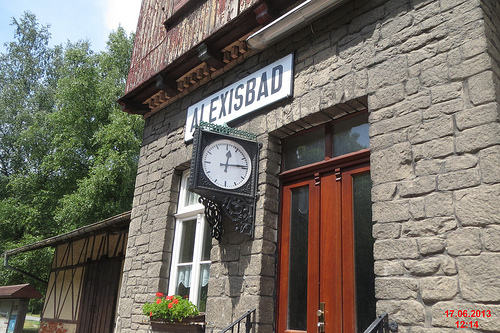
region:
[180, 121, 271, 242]
a metal and white clock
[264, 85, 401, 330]
a red wooden and glass door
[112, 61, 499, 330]
a grey stone building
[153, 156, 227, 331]
window in a stone building with white trim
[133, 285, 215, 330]
box planter with red and green flowers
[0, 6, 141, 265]
leafy green tree tops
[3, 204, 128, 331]
a wooden and tan building with a brown wooden door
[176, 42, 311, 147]
a white sign with black writing saying "ALEXISBAD"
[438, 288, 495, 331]
time stamp with red number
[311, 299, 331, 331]
a brass metal door knob and lock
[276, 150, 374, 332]
A brown front door with two long windows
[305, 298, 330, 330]
Silver lock and handle on the door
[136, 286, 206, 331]
A flower box filled with green leaves and red flowers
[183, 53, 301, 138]
A white sign with black letters that read ALEXISBAD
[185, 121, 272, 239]
An ornate clock on the stone wall front of the building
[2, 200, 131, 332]
A smaller building on the left side of the stone building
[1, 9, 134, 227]
Tall green trees in the background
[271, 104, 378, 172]
Two small windows above the door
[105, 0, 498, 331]
A gray stone building with an older messy looking top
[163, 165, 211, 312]
A white window in the stone building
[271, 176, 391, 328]
the door is closed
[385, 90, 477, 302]
the wall is made of stones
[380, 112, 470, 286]
the wall is rough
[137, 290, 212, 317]
the flowers are red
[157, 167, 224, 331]
window pane is white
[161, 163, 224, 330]
the window is closed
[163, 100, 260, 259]
a clock on the wall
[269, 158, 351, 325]
door frame is brown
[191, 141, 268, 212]
12:14 on the clock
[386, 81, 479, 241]
the wall is gray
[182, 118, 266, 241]
Black decorative clock mounted on wall of building.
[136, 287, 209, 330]
Red flowers growing in window box.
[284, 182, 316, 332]
Window inlaid in door.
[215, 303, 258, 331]
Black wrought iron railings on steps.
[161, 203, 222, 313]
White framed window in front of building.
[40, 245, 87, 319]
Tudor style design on front of building.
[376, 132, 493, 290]
Stone work on front of building next to front door.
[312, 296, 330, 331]
Door knob on front door.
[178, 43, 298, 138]
White sign with business name written in black.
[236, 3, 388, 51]
Light mounted under roof eaves.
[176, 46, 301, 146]
white rectangle sign on building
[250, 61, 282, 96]
black letters on white sign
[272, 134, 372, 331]
wood doors with glass windows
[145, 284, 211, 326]
flowers in window box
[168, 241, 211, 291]
white curtains in window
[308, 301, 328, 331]
knob on front door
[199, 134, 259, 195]
white faced clock on building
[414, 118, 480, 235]
gray stones on building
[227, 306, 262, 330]
metal rail attached to building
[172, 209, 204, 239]
white wood window frame